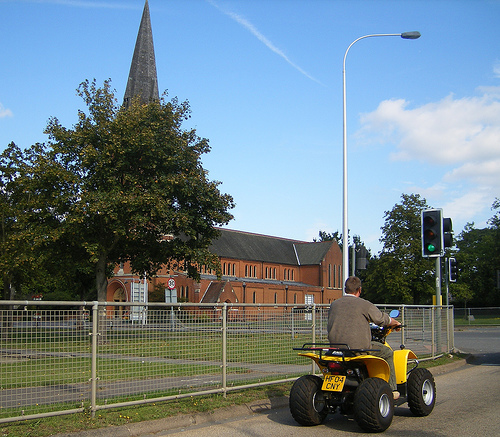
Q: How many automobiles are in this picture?
A: One.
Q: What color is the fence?
A: Silver.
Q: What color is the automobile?
A: Yellow.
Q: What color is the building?
A: Brown.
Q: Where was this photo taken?
A: On a street, near a building.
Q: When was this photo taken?
A: Outside, during the daytime.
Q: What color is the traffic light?
A: Green.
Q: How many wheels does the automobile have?
A: Four.